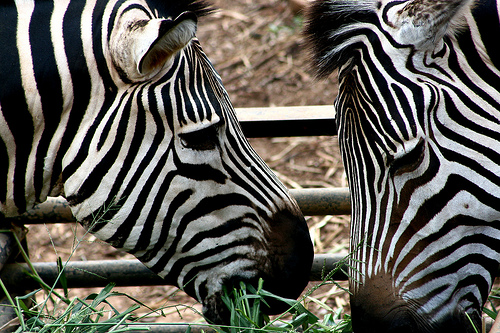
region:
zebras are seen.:
[80, 80, 421, 247]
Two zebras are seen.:
[52, 128, 412, 321]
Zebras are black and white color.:
[22, 52, 98, 144]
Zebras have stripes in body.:
[23, 82, 158, 189]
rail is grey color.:
[247, 95, 339, 153]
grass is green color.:
[32, 280, 138, 330]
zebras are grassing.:
[150, 230, 495, 330]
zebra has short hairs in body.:
[298, 0, 374, 77]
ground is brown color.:
[220, 20, 306, 86]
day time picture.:
[23, 31, 481, 296]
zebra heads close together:
[92, 30, 483, 325]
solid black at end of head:
[190, 197, 460, 327]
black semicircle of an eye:
[170, 115, 235, 155]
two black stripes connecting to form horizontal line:
[155, 136, 230, 201]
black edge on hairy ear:
[125, 6, 230, 71]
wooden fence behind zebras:
[20, 87, 422, 292]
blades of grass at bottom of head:
[147, 95, 342, 325]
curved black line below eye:
[381, 127, 441, 187]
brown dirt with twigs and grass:
[226, 10, 306, 95]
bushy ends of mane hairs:
[277, 5, 340, 80]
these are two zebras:
[15, 6, 490, 294]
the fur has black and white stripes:
[6, 22, 73, 96]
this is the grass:
[43, 293, 133, 331]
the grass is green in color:
[46, 307, 115, 330]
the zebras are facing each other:
[165, 132, 475, 315]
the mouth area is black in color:
[268, 213, 315, 303]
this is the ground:
[271, 134, 334, 167]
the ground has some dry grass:
[276, 138, 332, 172]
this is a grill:
[299, 188, 348, 206]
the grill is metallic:
[312, 189, 345, 215]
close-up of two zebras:
[0, 1, 497, 332]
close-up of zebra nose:
[265, 206, 315, 314]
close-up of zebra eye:
[175, 113, 225, 152]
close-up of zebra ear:
[115, 11, 202, 76]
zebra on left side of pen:
[0, 1, 314, 328]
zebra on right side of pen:
[304, 0, 499, 332]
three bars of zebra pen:
[0, 101, 347, 286]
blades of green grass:
[0, 206, 499, 332]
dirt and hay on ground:
[23, 0, 498, 332]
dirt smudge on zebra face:
[459, 200, 471, 210]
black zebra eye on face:
[168, 111, 235, 165]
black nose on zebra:
[267, 218, 319, 292]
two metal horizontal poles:
[311, 178, 341, 281]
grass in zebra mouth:
[212, 278, 279, 320]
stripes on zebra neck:
[17, 17, 95, 154]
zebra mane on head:
[302, 5, 379, 85]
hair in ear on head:
[153, 18, 195, 68]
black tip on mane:
[299, 3, 334, 72]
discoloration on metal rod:
[311, 188, 342, 213]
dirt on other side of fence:
[228, 19, 291, 96]